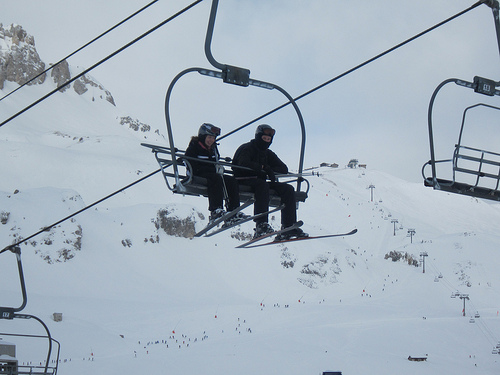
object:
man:
[231, 124, 310, 242]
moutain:
[0, 0, 500, 375]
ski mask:
[256, 133, 274, 150]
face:
[259, 132, 272, 147]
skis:
[235, 220, 359, 248]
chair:
[421, 144, 498, 201]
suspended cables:
[0, 2, 497, 254]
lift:
[421, 74, 498, 201]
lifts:
[136, 66, 317, 208]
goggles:
[203, 124, 221, 136]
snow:
[0, 0, 497, 375]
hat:
[198, 122, 220, 139]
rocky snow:
[0, 0, 500, 375]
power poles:
[366, 182, 470, 316]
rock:
[155, 212, 193, 238]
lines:
[0, 0, 201, 126]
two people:
[186, 122, 309, 242]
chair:
[1, 341, 60, 374]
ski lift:
[139, 0, 320, 211]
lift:
[2, 245, 60, 374]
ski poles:
[275, 171, 322, 177]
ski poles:
[214, 148, 230, 209]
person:
[182, 122, 250, 227]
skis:
[193, 200, 257, 238]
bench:
[140, 143, 310, 209]